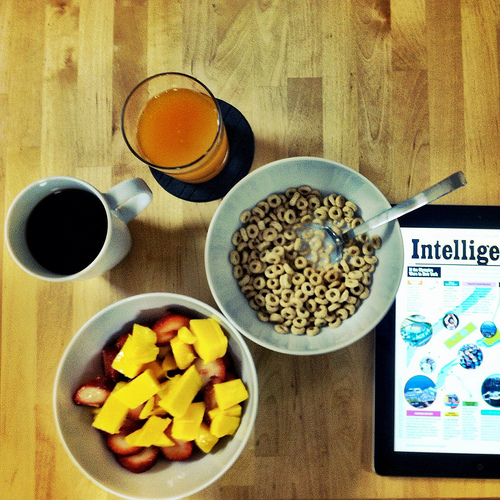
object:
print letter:
[408, 237, 420, 259]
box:
[371, 195, 499, 483]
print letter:
[419, 241, 432, 261]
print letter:
[451, 237, 461, 259]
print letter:
[460, 237, 468, 261]